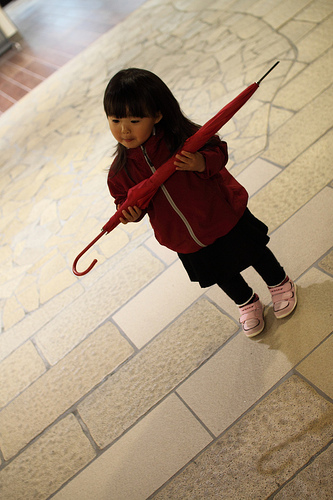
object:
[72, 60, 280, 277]
umbrella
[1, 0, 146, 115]
tiles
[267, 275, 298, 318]
sneakers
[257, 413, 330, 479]
stain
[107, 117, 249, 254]
hoodie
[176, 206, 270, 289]
skirt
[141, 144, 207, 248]
zipper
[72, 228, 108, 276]
umbrella hook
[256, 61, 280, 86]
point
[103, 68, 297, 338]
girl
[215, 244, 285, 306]
tights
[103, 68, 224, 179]
hair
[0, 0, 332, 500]
floor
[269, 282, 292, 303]
velco straps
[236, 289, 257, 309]
socks